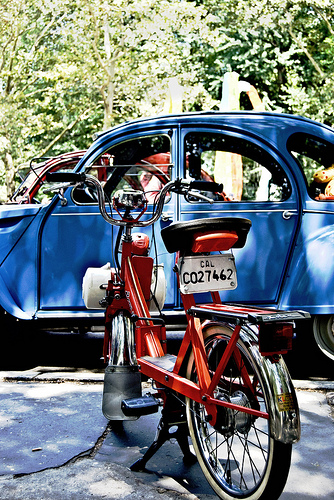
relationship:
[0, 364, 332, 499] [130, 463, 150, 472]
ground has gaps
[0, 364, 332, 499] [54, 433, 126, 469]
ground has cracks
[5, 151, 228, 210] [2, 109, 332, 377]
car beside car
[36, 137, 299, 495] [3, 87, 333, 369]
bike near blue car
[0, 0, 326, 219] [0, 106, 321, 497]
trees around area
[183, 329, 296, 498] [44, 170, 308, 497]
wheel of bike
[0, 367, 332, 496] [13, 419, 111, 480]
sidewalk has a crack